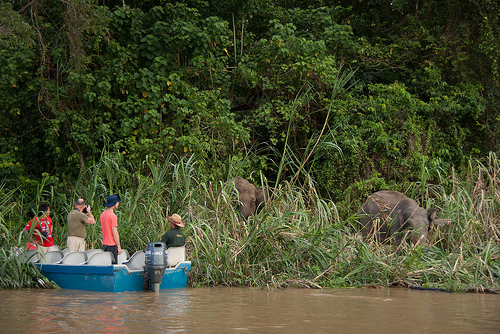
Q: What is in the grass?
A: Elephants.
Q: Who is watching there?
A: Tourists.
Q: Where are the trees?
A: Background.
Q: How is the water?
A: Murky.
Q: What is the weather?
A: Fair.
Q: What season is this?
A: Summer.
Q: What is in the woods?
A: Elephants.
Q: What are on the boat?
A: Chairs.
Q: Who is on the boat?
A: 4 men.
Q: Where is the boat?
A: Lake.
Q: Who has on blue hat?
A: A man.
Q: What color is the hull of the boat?
A: Blue.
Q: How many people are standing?
A: Three.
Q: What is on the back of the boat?
A: A motor.